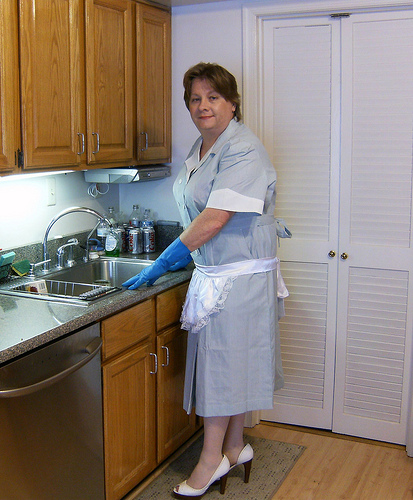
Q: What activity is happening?
A: Cleaning.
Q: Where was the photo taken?
A: Kitchen.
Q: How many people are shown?
A: One.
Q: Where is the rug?
A: Floor.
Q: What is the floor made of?
A: Wood.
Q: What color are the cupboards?
A: Brown.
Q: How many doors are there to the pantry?
A: Two.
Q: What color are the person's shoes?
A: White.